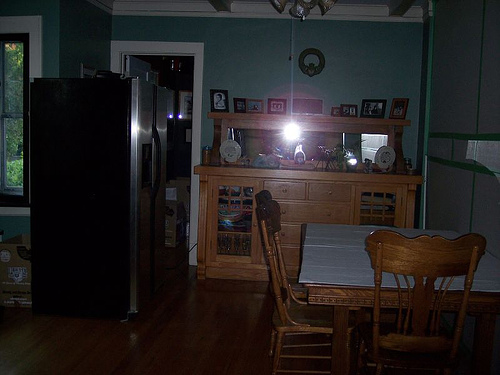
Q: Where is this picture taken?
A: A kitchen.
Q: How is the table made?
A: Of wood.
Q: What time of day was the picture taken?
A: Afternoon.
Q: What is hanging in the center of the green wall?
A: A wreath.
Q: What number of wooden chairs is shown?
A: Two.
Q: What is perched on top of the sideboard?
A: Photographs.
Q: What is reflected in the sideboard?
A: Camera flash.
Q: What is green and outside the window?
A: Trees.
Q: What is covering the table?
A: White tablecloth.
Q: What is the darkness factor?
A: Very dark.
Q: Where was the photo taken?
A: In a room.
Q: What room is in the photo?
A: Kitchen.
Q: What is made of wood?
A: Dining table.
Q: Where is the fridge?
A: In the room.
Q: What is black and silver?
A: The fridge.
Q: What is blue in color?
A: The wall.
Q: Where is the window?
A: On the wall.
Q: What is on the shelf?
A: Pictures.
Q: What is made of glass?
A: Cupboard door.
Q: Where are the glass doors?
A: On the wooden stand.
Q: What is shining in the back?
A: Flash,.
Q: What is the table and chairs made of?
A: Wood.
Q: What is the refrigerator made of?
A: Stainless steel.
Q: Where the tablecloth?
A: On table.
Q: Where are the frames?
A: On shelf.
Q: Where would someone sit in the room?
A: Chairs.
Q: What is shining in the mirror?
A: A light.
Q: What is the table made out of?
A: Wood.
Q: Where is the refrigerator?
A: On the left.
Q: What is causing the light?
A: A camera flash.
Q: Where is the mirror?
A: In the sideboard.